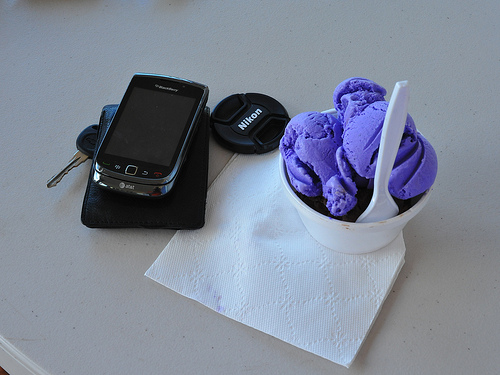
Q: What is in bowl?
A: Ice cream.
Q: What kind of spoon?
A: Plastic.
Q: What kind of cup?
A: Styrofoam.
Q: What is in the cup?
A: Frozen yogurt.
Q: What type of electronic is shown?
A: Phone.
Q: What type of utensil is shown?
A: Plastic.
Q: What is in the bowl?
A: Ice cream.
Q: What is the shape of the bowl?
A: Round.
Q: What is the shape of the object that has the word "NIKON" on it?
A: Round.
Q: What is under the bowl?
A: Napkin.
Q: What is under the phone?
A: Phone case.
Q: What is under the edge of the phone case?
A: Key.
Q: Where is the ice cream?
A: In the bowl.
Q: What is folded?
A: The napkin.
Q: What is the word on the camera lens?
A: Nikon.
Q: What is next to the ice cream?
A: Cellphone, key, and wallet.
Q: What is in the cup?
A: Ice cream.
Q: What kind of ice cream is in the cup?
A: Purple ice cream.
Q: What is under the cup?
A: Napkin.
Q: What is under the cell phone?
A: Wallet.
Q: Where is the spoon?
A: In the bowl.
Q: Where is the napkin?
A: On the table.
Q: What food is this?
A: Ice cream.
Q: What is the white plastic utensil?
A: Spoon.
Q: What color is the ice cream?
A: Purple.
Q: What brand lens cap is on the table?
A: Nikon.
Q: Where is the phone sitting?
A: On Wallet.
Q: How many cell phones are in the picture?
A: 1.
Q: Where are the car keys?
A: Under wallet.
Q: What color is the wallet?
A: Black.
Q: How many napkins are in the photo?
A: 1.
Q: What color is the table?
A: White.